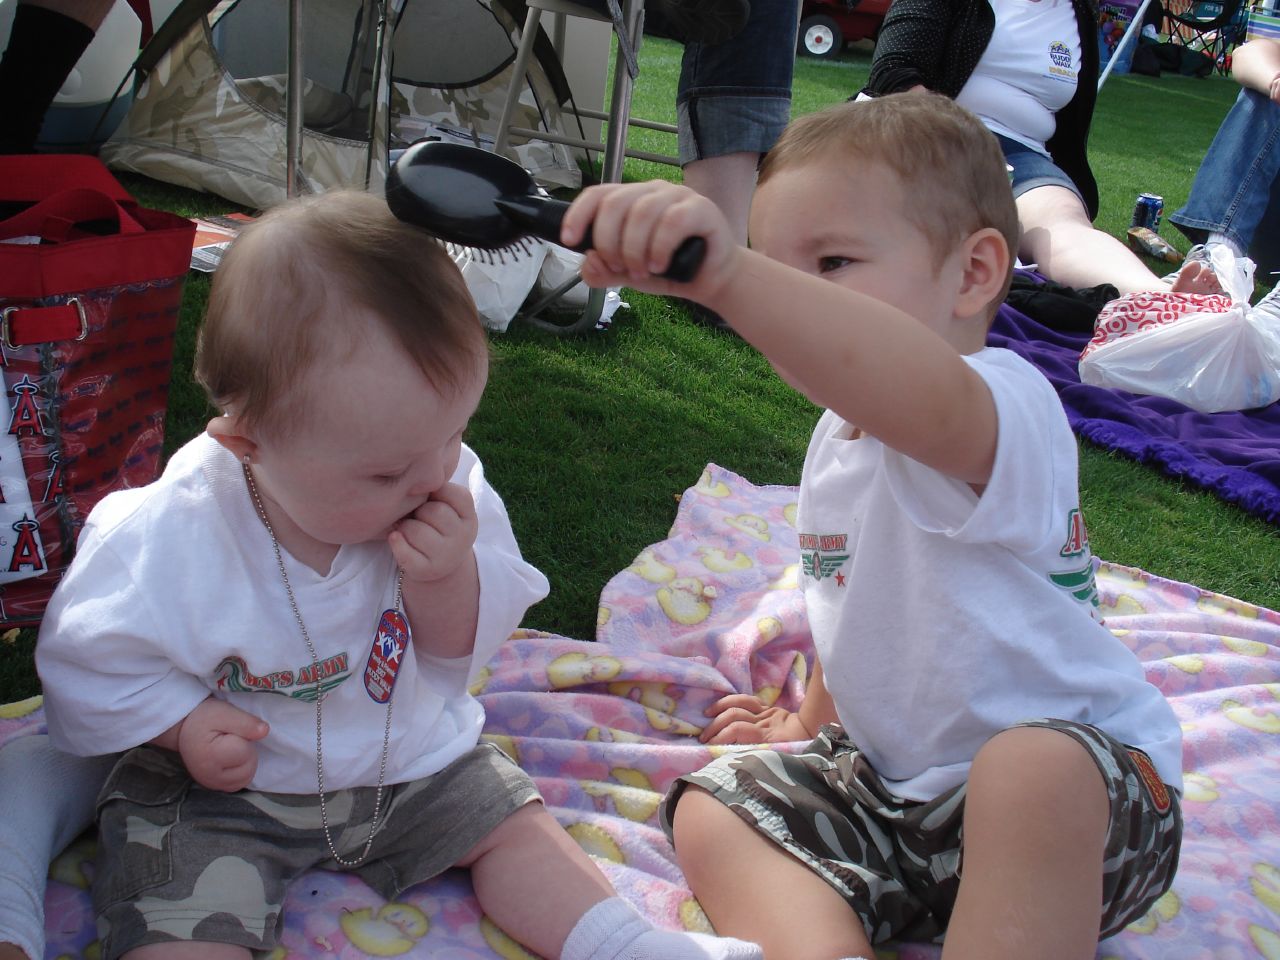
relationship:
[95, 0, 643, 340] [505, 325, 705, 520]
fence set up on grass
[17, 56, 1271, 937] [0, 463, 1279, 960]
children sitting on blanket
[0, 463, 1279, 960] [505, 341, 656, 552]
blanket in grass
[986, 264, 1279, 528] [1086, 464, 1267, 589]
blanket on ground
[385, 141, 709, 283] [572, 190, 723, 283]
bristle brush on hand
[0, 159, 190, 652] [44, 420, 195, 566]
bag on back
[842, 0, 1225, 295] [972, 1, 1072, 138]
people wearing shirt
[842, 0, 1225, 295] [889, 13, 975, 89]
people wearing sweater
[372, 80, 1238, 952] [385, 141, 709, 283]
boy holding bristle brush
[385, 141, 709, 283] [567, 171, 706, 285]
bristle brush in hand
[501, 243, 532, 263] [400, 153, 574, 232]
bristle on hair brush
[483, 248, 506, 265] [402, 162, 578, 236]
bristle on hair brush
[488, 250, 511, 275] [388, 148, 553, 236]
bristle on hair brush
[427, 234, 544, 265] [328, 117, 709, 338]
bristle on hair brush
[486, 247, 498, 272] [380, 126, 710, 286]
bristle on hair brush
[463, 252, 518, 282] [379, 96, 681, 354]
bristle on brush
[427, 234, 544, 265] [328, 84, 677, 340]
bristle on brush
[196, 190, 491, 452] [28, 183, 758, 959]
hair on baby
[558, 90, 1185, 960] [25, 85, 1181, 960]
boy brushing children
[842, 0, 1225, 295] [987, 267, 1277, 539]
people sitting on blanket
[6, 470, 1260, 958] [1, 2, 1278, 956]
blanket on ground